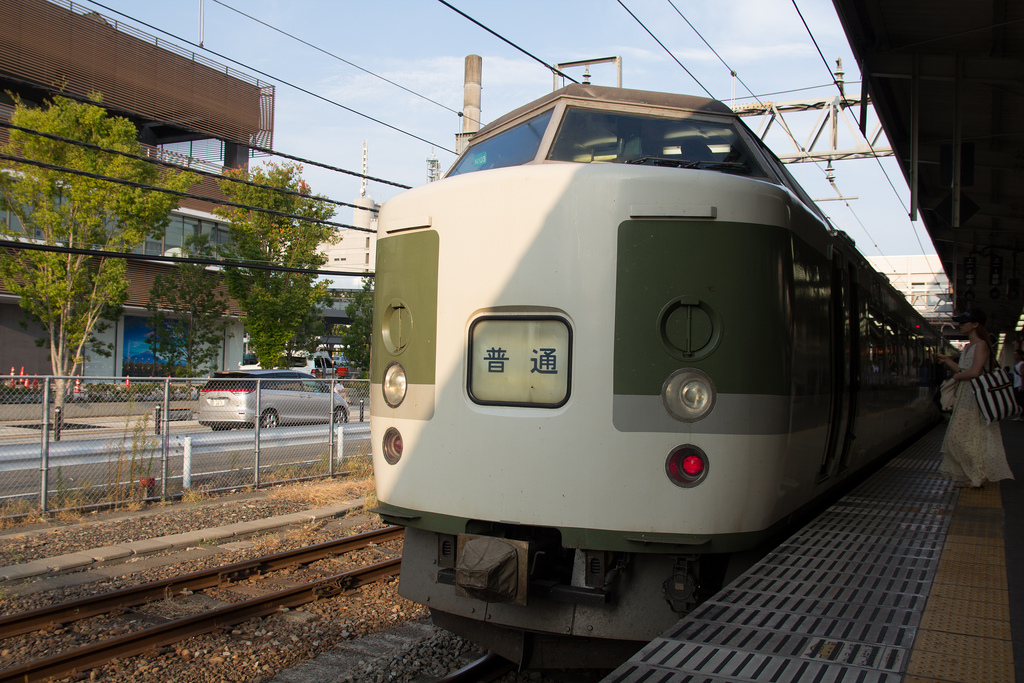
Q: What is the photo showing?
A: It is showing a station.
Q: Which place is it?
A: It is a station.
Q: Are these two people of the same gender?
A: Yes, all the people are female.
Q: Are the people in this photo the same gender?
A: Yes, all the people are female.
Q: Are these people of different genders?
A: No, all the people are female.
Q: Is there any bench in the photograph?
A: No, there are no benches.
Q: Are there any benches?
A: No, there are no benches.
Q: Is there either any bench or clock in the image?
A: No, there are no benches or clocks.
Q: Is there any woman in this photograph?
A: Yes, there is a woman.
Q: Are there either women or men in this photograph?
A: Yes, there is a woman.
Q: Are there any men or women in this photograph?
A: Yes, there is a woman.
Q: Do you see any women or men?
A: Yes, there is a woman.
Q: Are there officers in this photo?
A: No, there are no officers.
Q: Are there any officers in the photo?
A: No, there are no officers.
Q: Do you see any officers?
A: No, there are no officers.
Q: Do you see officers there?
A: No, there are no officers.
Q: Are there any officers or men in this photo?
A: No, there are no officers or men.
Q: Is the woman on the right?
A: Yes, the woman is on the right of the image.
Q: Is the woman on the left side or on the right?
A: The woman is on the right of the image.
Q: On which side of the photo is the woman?
A: The woman is on the right of the image.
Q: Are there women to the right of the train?
A: Yes, there is a woman to the right of the train.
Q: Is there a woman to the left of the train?
A: No, the woman is to the right of the train.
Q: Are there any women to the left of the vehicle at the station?
A: No, the woman is to the right of the train.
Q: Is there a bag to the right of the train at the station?
A: No, there is a woman to the right of the train.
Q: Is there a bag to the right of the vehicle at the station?
A: No, there is a woman to the right of the train.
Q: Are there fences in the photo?
A: Yes, there is a fence.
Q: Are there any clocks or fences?
A: Yes, there is a fence.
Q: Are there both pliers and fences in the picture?
A: No, there is a fence but no pliers.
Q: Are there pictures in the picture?
A: No, there are no pictures.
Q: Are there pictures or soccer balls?
A: No, there are no pictures or soccer balls.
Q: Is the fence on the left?
A: Yes, the fence is on the left of the image.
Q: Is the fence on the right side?
A: No, the fence is on the left of the image.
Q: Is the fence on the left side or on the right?
A: The fence is on the left of the image.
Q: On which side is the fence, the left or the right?
A: The fence is on the left of the image.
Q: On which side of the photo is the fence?
A: The fence is on the left of the image.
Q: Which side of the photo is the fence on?
A: The fence is on the left of the image.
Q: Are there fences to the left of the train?
A: Yes, there is a fence to the left of the train.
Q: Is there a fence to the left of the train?
A: Yes, there is a fence to the left of the train.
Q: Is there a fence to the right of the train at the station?
A: No, the fence is to the left of the train.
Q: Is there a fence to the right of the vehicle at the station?
A: No, the fence is to the left of the train.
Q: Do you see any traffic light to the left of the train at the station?
A: No, there is a fence to the left of the train.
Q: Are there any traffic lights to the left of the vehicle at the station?
A: No, there is a fence to the left of the train.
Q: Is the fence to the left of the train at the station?
A: Yes, the fence is to the left of the train.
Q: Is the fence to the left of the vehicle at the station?
A: Yes, the fence is to the left of the train.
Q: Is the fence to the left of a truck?
A: No, the fence is to the left of the train.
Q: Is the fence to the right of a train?
A: No, the fence is to the left of a train.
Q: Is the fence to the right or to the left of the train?
A: The fence is to the left of the train.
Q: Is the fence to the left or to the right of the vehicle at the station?
A: The fence is to the left of the train.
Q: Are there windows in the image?
A: Yes, there are windows.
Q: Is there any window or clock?
A: Yes, there are windows.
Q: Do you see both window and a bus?
A: No, there are windows but no buses.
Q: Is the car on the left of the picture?
A: Yes, the car is on the left of the image.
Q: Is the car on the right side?
A: No, the car is on the left of the image.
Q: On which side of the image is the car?
A: The car is on the left of the image.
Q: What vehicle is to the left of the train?
A: The vehicle is a car.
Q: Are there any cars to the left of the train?
A: Yes, there is a car to the left of the train.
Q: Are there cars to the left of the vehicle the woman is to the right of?
A: Yes, there is a car to the left of the train.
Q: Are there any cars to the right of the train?
A: No, the car is to the left of the train.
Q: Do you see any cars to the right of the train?
A: No, the car is to the left of the train.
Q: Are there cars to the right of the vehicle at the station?
A: No, the car is to the left of the train.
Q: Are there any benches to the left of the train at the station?
A: No, there is a car to the left of the train.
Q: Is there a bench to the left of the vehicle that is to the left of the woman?
A: No, there is a car to the left of the train.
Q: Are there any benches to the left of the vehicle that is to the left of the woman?
A: No, there is a car to the left of the train.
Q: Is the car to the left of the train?
A: Yes, the car is to the left of the train.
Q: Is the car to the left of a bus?
A: No, the car is to the left of the train.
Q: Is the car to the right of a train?
A: No, the car is to the left of a train.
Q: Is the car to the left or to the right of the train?
A: The car is to the left of the train.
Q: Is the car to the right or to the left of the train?
A: The car is to the left of the train.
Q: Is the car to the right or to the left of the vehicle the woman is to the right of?
A: The car is to the left of the train.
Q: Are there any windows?
A: Yes, there is a window.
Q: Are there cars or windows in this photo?
A: Yes, there is a window.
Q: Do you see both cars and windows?
A: Yes, there are both a window and a car.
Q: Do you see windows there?
A: Yes, there is a window.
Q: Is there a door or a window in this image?
A: Yes, there is a window.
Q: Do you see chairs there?
A: No, there are no chairs.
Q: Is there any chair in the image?
A: No, there are no chairs.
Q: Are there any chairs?
A: No, there are no chairs.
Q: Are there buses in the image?
A: No, there are no buses.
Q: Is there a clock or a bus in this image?
A: No, there are no buses or clocks.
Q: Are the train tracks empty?
A: Yes, the train tracks are empty.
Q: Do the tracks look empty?
A: Yes, the tracks are empty.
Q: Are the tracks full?
A: No, the tracks are empty.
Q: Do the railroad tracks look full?
A: No, the railroad tracks are empty.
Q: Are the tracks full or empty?
A: The tracks are empty.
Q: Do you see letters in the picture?
A: Yes, there are letters.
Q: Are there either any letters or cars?
A: Yes, there are letters.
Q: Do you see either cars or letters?
A: Yes, there are letters.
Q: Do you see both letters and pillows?
A: No, there are letters but no pillows.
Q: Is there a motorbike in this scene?
A: No, there are no motorcycles.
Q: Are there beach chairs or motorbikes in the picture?
A: No, there are no motorbikes or beach chairs.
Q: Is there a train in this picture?
A: Yes, there is a train.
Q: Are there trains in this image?
A: Yes, there is a train.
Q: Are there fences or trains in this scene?
A: Yes, there is a train.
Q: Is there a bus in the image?
A: No, there are no buses.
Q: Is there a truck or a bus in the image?
A: No, there are no buses or trucks.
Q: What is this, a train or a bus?
A: This is a train.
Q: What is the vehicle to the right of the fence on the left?
A: The vehicle is a train.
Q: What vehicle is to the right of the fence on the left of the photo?
A: The vehicle is a train.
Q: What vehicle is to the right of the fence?
A: The vehicle is a train.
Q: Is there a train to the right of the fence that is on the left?
A: Yes, there is a train to the right of the fence.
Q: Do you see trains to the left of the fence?
A: No, the train is to the right of the fence.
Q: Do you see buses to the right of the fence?
A: No, there is a train to the right of the fence.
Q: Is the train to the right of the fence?
A: Yes, the train is to the right of the fence.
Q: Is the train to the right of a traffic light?
A: No, the train is to the right of the fence.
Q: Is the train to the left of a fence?
A: No, the train is to the right of a fence.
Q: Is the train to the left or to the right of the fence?
A: The train is to the right of the fence.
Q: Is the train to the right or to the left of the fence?
A: The train is to the right of the fence.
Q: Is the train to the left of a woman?
A: Yes, the train is to the left of a woman.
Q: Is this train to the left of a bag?
A: No, the train is to the left of a woman.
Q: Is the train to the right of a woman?
A: No, the train is to the left of a woman.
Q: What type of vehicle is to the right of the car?
A: The vehicle is a train.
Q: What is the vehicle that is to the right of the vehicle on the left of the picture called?
A: The vehicle is a train.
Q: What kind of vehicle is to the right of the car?
A: The vehicle is a train.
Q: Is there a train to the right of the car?
A: Yes, there is a train to the right of the car.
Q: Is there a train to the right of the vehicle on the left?
A: Yes, there is a train to the right of the car.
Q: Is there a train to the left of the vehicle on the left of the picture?
A: No, the train is to the right of the car.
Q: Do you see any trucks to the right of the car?
A: No, there is a train to the right of the car.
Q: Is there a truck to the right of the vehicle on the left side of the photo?
A: No, there is a train to the right of the car.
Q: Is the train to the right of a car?
A: Yes, the train is to the right of a car.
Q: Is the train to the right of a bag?
A: No, the train is to the right of a car.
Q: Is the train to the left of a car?
A: No, the train is to the right of a car.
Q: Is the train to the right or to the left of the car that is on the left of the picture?
A: The train is to the right of the car.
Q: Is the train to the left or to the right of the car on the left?
A: The train is to the right of the car.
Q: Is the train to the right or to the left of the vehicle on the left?
A: The train is to the right of the car.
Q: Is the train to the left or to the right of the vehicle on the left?
A: The train is to the right of the car.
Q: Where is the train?
A: The train is at the station.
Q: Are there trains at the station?
A: Yes, there is a train at the station.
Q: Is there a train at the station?
A: Yes, there is a train at the station.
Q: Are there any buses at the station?
A: No, there is a train at the station.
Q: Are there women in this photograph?
A: Yes, there is a woman.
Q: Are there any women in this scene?
A: Yes, there is a woman.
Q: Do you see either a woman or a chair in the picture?
A: Yes, there is a woman.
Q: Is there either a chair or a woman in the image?
A: Yes, there is a woman.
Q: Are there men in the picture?
A: No, there are no men.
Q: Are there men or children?
A: No, there are no men or children.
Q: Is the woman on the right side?
A: Yes, the woman is on the right of the image.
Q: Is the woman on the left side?
A: No, the woman is on the right of the image.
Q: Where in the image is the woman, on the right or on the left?
A: The woman is on the right of the image.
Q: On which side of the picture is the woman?
A: The woman is on the right of the image.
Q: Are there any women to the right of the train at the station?
A: Yes, there is a woman to the right of the train.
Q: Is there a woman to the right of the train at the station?
A: Yes, there is a woman to the right of the train.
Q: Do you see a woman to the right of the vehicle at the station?
A: Yes, there is a woman to the right of the train.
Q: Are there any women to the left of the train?
A: No, the woman is to the right of the train.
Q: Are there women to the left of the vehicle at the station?
A: No, the woman is to the right of the train.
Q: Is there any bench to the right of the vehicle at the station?
A: No, there is a woman to the right of the train.